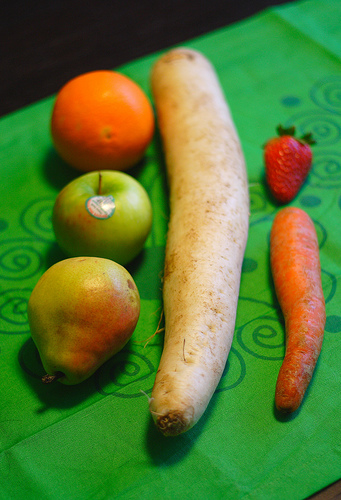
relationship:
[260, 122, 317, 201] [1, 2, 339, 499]
strawberry on top of cloth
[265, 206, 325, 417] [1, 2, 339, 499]
carrot on top of cloth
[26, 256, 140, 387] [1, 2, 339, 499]
pear on top of cloth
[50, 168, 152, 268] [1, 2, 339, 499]
apple on top of cloth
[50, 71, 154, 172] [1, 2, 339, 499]
orange on top of cloth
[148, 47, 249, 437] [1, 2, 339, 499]
parsnip on top of cloth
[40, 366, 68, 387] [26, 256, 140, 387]
stem of pear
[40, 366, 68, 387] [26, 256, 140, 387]
stem on top of pear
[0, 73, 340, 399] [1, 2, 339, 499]
design printed on cloth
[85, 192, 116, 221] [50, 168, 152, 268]
label stuck on apple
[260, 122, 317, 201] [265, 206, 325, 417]
strawberry above carrot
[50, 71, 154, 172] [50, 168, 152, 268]
orange above apple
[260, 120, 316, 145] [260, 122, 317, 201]
stem on top of strawberry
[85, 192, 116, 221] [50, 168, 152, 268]
label on top of apple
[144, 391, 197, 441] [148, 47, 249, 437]
roots on parsnip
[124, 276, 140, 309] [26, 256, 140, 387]
bruise on side of pear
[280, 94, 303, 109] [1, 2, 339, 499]
dot on cloth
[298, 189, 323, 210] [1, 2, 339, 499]
dot on cloth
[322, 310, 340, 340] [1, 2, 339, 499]
dot on cloth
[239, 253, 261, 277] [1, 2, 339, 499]
dot on cloth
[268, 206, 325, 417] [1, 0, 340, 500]
carrot on top of table